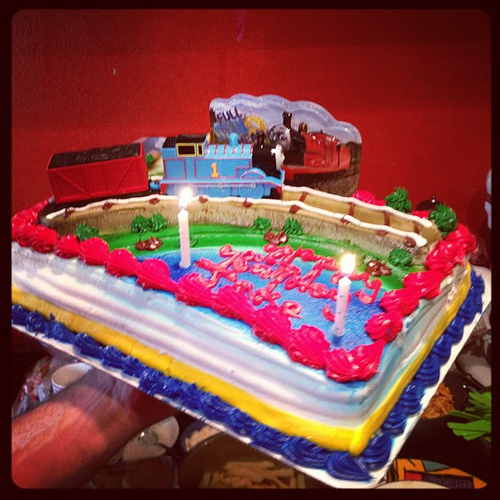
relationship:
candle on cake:
[174, 186, 199, 272] [8, 90, 494, 489]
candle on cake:
[327, 251, 360, 341] [8, 90, 494, 489]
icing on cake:
[12, 195, 480, 386] [8, 90, 494, 489]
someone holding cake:
[10, 363, 185, 490] [8, 90, 494, 489]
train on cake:
[157, 130, 294, 205] [8, 90, 494, 489]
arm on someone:
[10, 378, 83, 490] [10, 363, 185, 490]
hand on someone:
[89, 363, 187, 427] [10, 363, 185, 490]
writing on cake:
[189, 241, 384, 324] [8, 90, 494, 489]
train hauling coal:
[157, 130, 294, 205] [45, 140, 141, 173]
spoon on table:
[136, 427, 187, 460] [13, 305, 497, 493]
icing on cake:
[0, 195, 499, 385] [8, 90, 494, 489]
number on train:
[206, 158, 224, 183] [157, 130, 294, 205]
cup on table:
[47, 360, 99, 397] [13, 305, 497, 493]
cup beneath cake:
[47, 360, 99, 397] [8, 90, 494, 489]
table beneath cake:
[13, 305, 497, 493] [8, 90, 494, 489]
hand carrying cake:
[89, 363, 187, 427] [8, 90, 494, 489]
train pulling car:
[157, 130, 294, 205] [41, 134, 152, 210]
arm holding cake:
[10, 378, 83, 490] [8, 90, 494, 489]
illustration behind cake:
[201, 90, 361, 193] [8, 90, 494, 489]